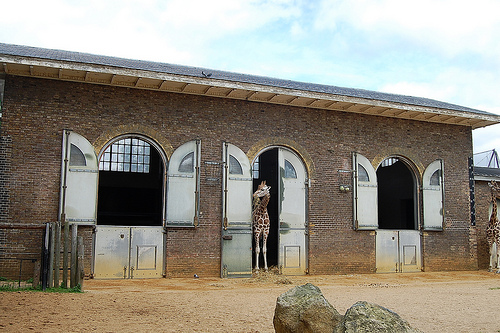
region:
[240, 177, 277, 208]
the head of a giraffe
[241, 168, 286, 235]
a brown spotted giraffe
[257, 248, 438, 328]
a rock near a giraffe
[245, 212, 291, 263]
the legs of a giraffe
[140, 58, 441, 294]
a giraffe in a building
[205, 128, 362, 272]
a giraffe looking out of a door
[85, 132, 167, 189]
a window in a building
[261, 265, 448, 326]
a big rock on the ground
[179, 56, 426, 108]
the roof of a building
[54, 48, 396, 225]
a big brick building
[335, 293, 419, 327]
rock on the ground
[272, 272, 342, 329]
rock on the ground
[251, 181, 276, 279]
giraffe in the door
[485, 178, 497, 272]
giraffe on the side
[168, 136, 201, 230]
half door open on side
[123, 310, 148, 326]
patch of dirt floor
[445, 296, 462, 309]
patch of dirt floor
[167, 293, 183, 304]
patch of dirt floor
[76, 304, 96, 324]
patch of dirt floor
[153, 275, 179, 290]
patch of dirt floor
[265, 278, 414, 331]
Two pieces of large rocks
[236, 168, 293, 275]
Small giraffe looking to the left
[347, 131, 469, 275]
Half open stable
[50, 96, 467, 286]
Three open stables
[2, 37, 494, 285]
Brown brick stable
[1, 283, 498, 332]
Dirt area of land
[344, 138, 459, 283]
White doors of stable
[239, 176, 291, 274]
Small brown and white giraffe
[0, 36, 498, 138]
Black tile roof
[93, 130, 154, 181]
Part of small window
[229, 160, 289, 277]
the giraffe is looking out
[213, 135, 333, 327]
the giraffe is looking out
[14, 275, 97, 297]
grass on the ground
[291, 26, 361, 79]
Sky is blue color.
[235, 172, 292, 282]
Giraffe is standing near the door step.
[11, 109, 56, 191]
Wall is brown color.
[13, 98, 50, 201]
Wall is made of bricks.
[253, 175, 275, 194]
Giraffe has two horns in the head.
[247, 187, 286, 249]
Brown spots in giraffe.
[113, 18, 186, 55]
Clouds are white color.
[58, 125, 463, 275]
Doors are grey color.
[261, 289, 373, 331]
Rock is brown color.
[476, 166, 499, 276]
Giraffe is standing near the wall.